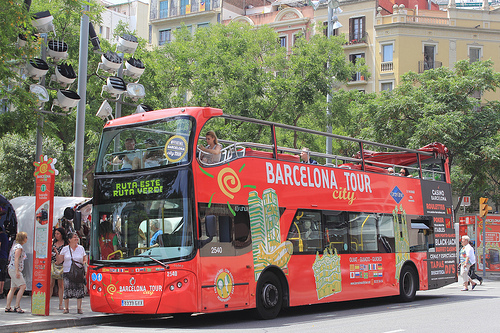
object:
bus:
[88, 106, 458, 321]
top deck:
[98, 100, 454, 184]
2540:
[210, 246, 223, 254]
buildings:
[245, 188, 410, 302]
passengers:
[109, 125, 421, 177]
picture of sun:
[199, 160, 257, 218]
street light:
[22, 4, 148, 135]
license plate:
[121, 299, 144, 306]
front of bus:
[85, 107, 198, 315]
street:
[14, 274, 498, 333]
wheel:
[249, 264, 291, 322]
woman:
[458, 235, 479, 294]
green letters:
[111, 179, 164, 196]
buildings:
[103, 1, 499, 83]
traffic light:
[479, 196, 489, 284]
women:
[54, 232, 87, 321]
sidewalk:
[2, 286, 94, 329]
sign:
[30, 149, 54, 315]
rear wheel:
[399, 260, 420, 302]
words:
[265, 161, 372, 203]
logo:
[389, 185, 404, 204]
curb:
[10, 312, 90, 332]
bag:
[66, 244, 86, 284]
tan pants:
[469, 266, 483, 281]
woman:
[198, 130, 223, 164]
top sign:
[164, 134, 189, 162]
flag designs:
[348, 256, 384, 286]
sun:
[217, 167, 242, 199]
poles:
[24, 8, 78, 187]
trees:
[1, 6, 499, 136]